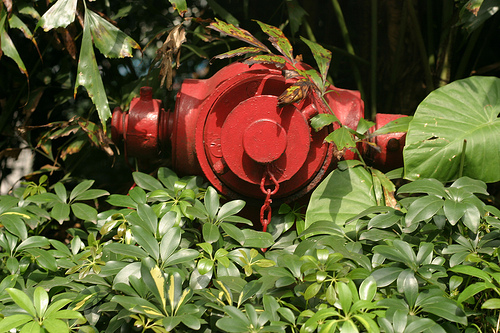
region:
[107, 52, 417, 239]
a red fire hydrant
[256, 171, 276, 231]
a red chain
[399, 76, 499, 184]
a large green leaf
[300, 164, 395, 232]
a large green leaf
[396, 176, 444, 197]
a small green leaf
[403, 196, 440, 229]
a small green leaf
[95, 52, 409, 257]
red hydrant with red chain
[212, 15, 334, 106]
yellowing leaves with brown spots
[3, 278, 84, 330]
green leaves spread open like a flower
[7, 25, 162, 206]
darkness between upper and lower leaves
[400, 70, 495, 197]
large oval leaf with ribbing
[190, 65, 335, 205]
round coverings over circular valves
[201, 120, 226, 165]
raised symbol on edge of cover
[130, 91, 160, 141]
light reflecting off hydrant band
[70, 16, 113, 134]
leaf with missing curved section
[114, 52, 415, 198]
Red fire hydrant in a bush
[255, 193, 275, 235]
Red chain on a fire hydrant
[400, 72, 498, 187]
A big green leaf on a bush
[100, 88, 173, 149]
Red connector on a fire hydrant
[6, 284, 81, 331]
Leaves shaped like a flower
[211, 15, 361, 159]
Brown and green leaves on a bush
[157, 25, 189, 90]
Brown leaf on a bush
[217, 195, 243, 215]
A green leaf on a bush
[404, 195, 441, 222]
A green leaf on a bush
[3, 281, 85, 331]
Leaves on a bush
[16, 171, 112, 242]
Green leaves on a bush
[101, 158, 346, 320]
Bright green leaves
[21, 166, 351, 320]
Green leaves outside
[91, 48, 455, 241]
Red fire hydrant in a bush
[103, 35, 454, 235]
Fire hydrant in a bush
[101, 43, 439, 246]
Red fire hydrant outside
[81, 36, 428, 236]
Fire hydrant outside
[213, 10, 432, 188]
Brown and green leaves on a plant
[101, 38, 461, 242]
Fire hydrant with a bush in front of it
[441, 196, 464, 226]
green leaf on plant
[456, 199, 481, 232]
green leaf on plant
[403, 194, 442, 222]
green leaf on plant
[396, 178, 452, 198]
green leaf on plant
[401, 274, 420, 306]
green leaf on plant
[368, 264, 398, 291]
green leaf on plant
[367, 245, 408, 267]
green leaf on plant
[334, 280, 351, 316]
green leaf on plant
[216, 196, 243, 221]
green leaf on plant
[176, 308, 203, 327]
green leaf on plant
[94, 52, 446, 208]
this is a fire hydrant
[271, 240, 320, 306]
these are leaves on a branch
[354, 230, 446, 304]
these are leaves on a branch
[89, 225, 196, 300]
these are leaves on a branch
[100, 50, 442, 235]
red metal water valve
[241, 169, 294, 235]
red painted metal chain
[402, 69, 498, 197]
large flat green leaf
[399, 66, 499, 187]
large green leaf with holes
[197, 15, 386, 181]
leafy green branch with brown spots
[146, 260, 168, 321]
yellow spot on green leaf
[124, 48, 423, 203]
Red fire hydrant in the bushes